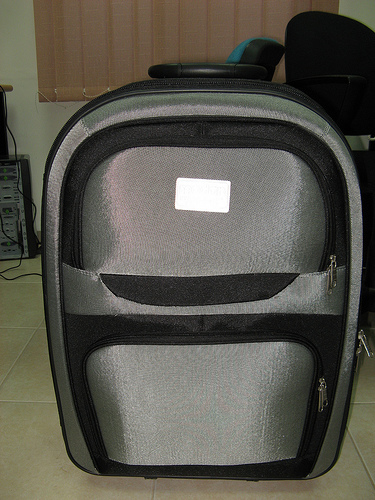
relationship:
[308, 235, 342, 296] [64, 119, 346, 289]
zipper on pocket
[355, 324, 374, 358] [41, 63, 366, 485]
zipper on bag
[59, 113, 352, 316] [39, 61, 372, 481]
pocket on bag